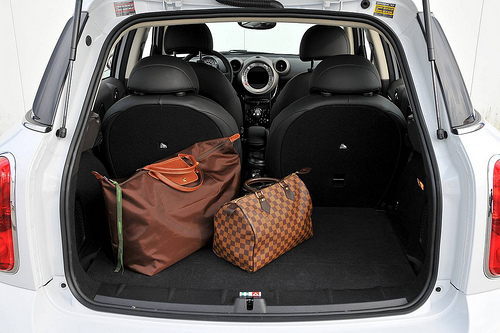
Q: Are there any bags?
A: Yes, there is a bag.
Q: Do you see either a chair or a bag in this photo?
A: Yes, there is a bag.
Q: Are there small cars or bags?
A: Yes, there is a small bag.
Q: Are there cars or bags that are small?
A: Yes, the bag is small.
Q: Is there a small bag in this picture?
A: Yes, there is a small bag.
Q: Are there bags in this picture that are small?
A: Yes, there is a bag that is small.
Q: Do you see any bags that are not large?
A: Yes, there is a small bag.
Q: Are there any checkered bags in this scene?
A: Yes, there is a checkered bag.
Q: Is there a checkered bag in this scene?
A: Yes, there is a checkered bag.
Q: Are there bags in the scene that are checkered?
A: Yes, there is a checkered bag.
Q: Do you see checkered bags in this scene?
A: Yes, there is a checkered bag.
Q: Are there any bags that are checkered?
A: Yes, there is a bag that is checkered.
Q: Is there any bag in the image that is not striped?
A: Yes, there is a checkered bag.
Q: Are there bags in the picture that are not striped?
A: Yes, there is a checkered bag.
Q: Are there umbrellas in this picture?
A: No, there are no umbrellas.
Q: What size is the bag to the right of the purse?
A: The bag is small.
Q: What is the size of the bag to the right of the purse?
A: The bag is small.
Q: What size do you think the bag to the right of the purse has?
A: The bag has small size.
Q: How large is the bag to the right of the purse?
A: The bag is small.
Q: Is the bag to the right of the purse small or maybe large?
A: The bag is small.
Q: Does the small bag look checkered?
A: Yes, the bag is checkered.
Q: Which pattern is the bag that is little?
A: The bag is checkered.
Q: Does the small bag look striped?
A: No, the bag is checkered.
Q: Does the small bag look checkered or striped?
A: The bag is checkered.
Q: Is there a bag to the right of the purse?
A: Yes, there is a bag to the right of the purse.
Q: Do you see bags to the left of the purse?
A: No, the bag is to the right of the purse.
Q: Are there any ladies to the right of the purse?
A: No, there is a bag to the right of the purse.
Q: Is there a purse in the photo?
A: Yes, there is a purse.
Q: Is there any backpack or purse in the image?
A: Yes, there is a purse.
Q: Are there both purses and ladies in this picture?
A: No, there is a purse but no ladies.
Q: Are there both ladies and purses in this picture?
A: No, there is a purse but no ladies.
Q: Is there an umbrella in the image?
A: No, there are no umbrellas.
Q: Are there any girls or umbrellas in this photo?
A: No, there are no umbrellas or girls.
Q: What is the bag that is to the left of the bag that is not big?
A: The bag is a purse.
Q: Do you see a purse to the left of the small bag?
A: Yes, there is a purse to the left of the bag.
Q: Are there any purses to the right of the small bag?
A: No, the purse is to the left of the bag.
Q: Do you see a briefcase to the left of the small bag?
A: No, there is a purse to the left of the bag.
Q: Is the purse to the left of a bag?
A: Yes, the purse is to the left of a bag.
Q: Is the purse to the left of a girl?
A: No, the purse is to the left of a bag.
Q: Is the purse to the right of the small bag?
A: No, the purse is to the left of the bag.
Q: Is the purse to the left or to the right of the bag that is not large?
A: The purse is to the left of the bag.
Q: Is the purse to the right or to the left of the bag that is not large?
A: The purse is to the left of the bag.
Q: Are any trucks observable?
A: No, there are no trucks.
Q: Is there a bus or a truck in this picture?
A: No, there are no trucks or buses.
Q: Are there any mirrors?
A: Yes, there is a mirror.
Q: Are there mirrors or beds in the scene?
A: Yes, there is a mirror.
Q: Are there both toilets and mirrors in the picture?
A: No, there is a mirror but no toilets.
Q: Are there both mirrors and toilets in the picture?
A: No, there is a mirror but no toilets.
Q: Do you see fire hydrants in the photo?
A: No, there are no fire hydrants.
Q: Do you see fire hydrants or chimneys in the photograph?
A: No, there are no fire hydrants or chimneys.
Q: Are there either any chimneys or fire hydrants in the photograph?
A: No, there are no fire hydrants or chimneys.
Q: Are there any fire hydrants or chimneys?
A: No, there are no fire hydrants or chimneys.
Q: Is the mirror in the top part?
A: Yes, the mirror is in the top of the image.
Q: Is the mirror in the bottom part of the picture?
A: No, the mirror is in the top of the image.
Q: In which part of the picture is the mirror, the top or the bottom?
A: The mirror is in the top of the image.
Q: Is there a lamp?
A: No, there are no lamps.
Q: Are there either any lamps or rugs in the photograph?
A: No, there are no lamps or rugs.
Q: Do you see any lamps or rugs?
A: No, there are no lamps or rugs.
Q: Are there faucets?
A: No, there are no faucets.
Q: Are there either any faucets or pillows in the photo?
A: No, there are no faucets or pillows.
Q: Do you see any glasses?
A: No, there are no glasses.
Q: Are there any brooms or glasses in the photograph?
A: No, there are no glasses or brooms.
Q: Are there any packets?
A: No, there are no packets.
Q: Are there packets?
A: No, there are no packets.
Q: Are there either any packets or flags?
A: No, there are no packets or flags.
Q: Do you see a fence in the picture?
A: No, there are no fences.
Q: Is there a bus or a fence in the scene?
A: No, there are no fences or buses.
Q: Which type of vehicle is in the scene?
A: The vehicle is a car.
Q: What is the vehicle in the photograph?
A: The vehicle is a car.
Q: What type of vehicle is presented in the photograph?
A: The vehicle is a car.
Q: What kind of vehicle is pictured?
A: The vehicle is a car.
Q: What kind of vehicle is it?
A: The vehicle is a car.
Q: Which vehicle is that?
A: That is a car.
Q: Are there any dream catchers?
A: No, there are no dream catchers.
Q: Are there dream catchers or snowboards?
A: No, there are no dream catchers or snowboards.